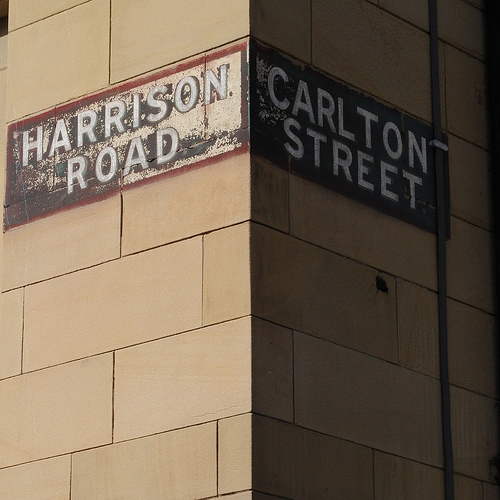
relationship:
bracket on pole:
[427, 140, 447, 152] [419, 3, 478, 498]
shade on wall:
[248, 1, 499, 499] [0, 0, 253, 499]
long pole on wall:
[426, 0, 455, 498] [277, 62, 484, 497]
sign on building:
[5, 39, 252, 234] [2, 2, 497, 498]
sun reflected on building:
[83, 331, 192, 453] [41, 342, 200, 492]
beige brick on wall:
[20, 233, 203, 377] [5, 231, 250, 493]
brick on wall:
[111, 314, 249, 443] [5, 231, 250, 493]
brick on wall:
[121, 152, 250, 257] [5, 231, 250, 493]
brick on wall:
[2, 350, 111, 472] [5, 231, 250, 493]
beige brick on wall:
[0, 191, 121, 295] [5, 231, 250, 493]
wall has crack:
[1, 144, 256, 497] [212, 424, 220, 489]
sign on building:
[249, 33, 452, 241] [2, 2, 497, 498]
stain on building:
[372, 270, 429, 365] [30, 40, 477, 458]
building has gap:
[23, 19, 464, 498] [118, 192, 124, 249]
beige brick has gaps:
[20, 233, 203, 377] [103, 347, 120, 447]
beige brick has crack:
[20, 233, 203, 377] [212, 421, 220, 498]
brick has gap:
[203, 221, 397, 360] [289, 330, 299, 425]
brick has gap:
[291, 329, 444, 466] [109, 350, 116, 440]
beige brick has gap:
[20, 233, 203, 377] [198, 232, 209, 329]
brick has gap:
[113, 316, 292, 438] [394, 277, 399, 363]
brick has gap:
[2, 350, 111, 472] [19, 283, 26, 375]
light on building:
[50, 218, 209, 455] [0, 3, 250, 497]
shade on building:
[276, 222, 426, 427] [248, 10, 498, 499]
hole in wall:
[369, 270, 395, 302] [253, 0, 499, 497]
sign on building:
[5, 36, 251, 234] [43, 31, 426, 325]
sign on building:
[225, 50, 446, 234] [4, 71, 499, 500]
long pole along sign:
[426, 0, 459, 498] [249, 33, 452, 241]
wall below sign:
[0, 0, 252, 499] [213, 32, 466, 225]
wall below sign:
[4, 233, 499, 496] [12, 112, 452, 254]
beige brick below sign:
[1, 227, 498, 498] [249, 33, 452, 241]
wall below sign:
[4, 233, 499, 496] [249, 33, 452, 241]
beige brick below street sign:
[4, 191, 496, 487] [6, 57, 455, 229]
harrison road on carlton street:
[21, 63, 227, 195] [265, 65, 427, 214]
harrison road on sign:
[23, 66, 225, 192] [6, 36, 253, 213]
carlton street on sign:
[271, 68, 427, 211] [239, 46, 374, 171]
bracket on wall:
[427, 140, 449, 157] [253, 0, 499, 497]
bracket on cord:
[427, 140, 449, 157] [427, 0, 456, 498]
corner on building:
[226, 3, 264, 498] [2, 2, 497, 498]